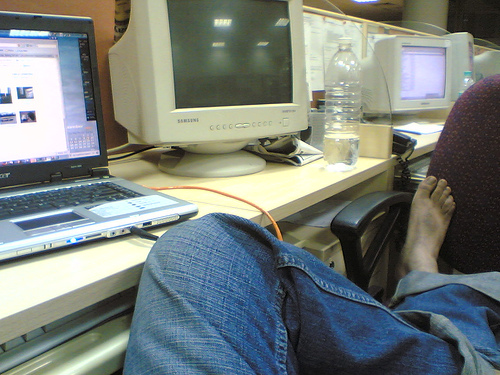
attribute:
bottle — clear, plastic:
[456, 69, 475, 98]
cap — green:
[462, 70, 472, 75]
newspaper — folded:
[256, 136, 323, 170]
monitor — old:
[361, 35, 453, 114]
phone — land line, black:
[378, 124, 426, 186]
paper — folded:
[251, 131, 324, 171]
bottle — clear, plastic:
[320, 28, 371, 170]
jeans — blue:
[82, 178, 499, 365]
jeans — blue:
[133, 202, 496, 365]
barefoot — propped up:
[392, 170, 458, 285]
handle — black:
[329, 190, 414, 305]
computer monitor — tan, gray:
[106, 3, 311, 180]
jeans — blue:
[122, 211, 497, 373]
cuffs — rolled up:
[390, 270, 499, 372]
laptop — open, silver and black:
[4, 12, 196, 253]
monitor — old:
[91, 25, 306, 110]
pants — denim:
[97, 192, 494, 372]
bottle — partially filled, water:
[323, 37, 360, 172]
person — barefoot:
[405, 163, 470, 253]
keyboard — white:
[17, 283, 109, 370]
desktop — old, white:
[0, 146, 378, 321]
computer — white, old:
[106, 0, 312, 179]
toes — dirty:
[415, 166, 457, 218]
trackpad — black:
[13, 210, 83, 231]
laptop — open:
[1, 7, 203, 269]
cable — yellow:
[142, 182, 283, 242]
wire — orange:
[150, 182, 282, 245]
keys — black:
[0, 178, 142, 219]